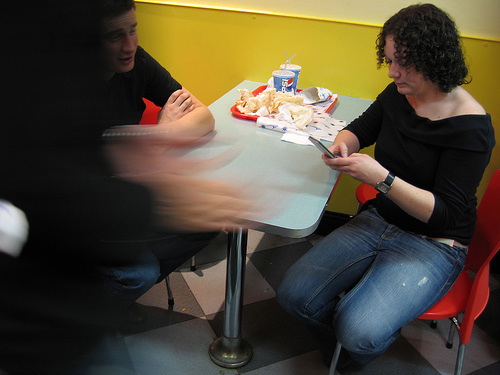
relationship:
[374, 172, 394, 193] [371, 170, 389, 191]
watch on wrist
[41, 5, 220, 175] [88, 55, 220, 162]
man with arms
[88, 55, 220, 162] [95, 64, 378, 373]
arms on table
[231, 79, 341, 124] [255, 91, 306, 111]
tray with food